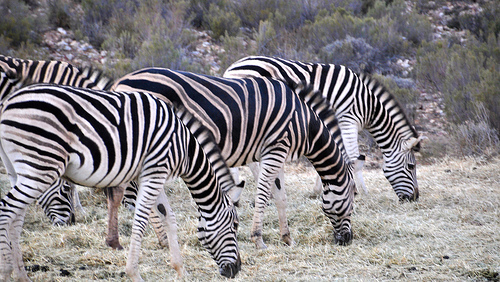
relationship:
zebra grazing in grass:
[7, 85, 252, 266] [29, 153, 484, 271]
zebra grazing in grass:
[117, 70, 357, 257] [29, 153, 484, 271]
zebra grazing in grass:
[221, 55, 427, 203] [29, 153, 484, 271]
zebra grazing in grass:
[4, 51, 140, 222] [29, 153, 484, 271]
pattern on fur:
[204, 73, 294, 153] [219, 90, 269, 140]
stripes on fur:
[119, 104, 179, 201] [63, 99, 154, 169]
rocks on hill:
[51, 18, 107, 65] [18, 11, 478, 161]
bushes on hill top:
[29, 19, 485, 113] [11, 14, 473, 155]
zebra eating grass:
[7, 85, 252, 266] [42, 167, 477, 272]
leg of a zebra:
[0, 153, 70, 281] [7, 85, 252, 266]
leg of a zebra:
[4, 170, 49, 266] [7, 85, 252, 266]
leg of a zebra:
[103, 189, 124, 256] [107, 72, 372, 251]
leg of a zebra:
[103, 189, 124, 247] [10, 88, 230, 270]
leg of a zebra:
[159, 206, 186, 273] [7, 85, 252, 266]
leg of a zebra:
[274, 186, 300, 248] [107, 72, 372, 251]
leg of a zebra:
[338, 120, 365, 198] [223, 43, 430, 207]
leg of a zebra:
[103, 189, 124, 247] [107, 72, 372, 251]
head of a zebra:
[200, 205, 249, 278] [7, 85, 252, 266]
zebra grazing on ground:
[7, 85, 252, 266] [14, 154, 484, 269]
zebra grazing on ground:
[109, 65, 359, 247] [58, 153, 469, 272]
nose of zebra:
[213, 259, 251, 276] [7, 85, 252, 266]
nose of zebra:
[330, 217, 356, 248] [107, 72, 372, 251]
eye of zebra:
[226, 217, 243, 234] [1, 76, 246, 280]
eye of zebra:
[352, 184, 361, 204] [101, 62, 367, 248]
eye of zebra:
[403, 161, 417, 170] [223, 43, 430, 207]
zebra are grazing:
[0, 85, 242, 282] [200, 157, 436, 274]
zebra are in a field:
[0, 85, 242, 282] [20, 159, 469, 270]